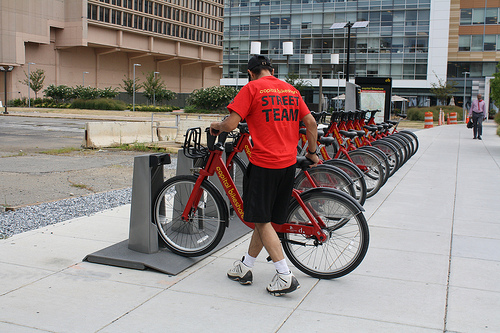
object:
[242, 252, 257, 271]
white sock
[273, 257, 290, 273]
white sock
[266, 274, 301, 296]
foot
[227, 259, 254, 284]
foot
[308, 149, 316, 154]
watch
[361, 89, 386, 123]
large map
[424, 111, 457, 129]
traffic cones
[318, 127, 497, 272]
street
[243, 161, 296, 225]
shorts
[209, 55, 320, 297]
man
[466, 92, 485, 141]
man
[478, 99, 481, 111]
tie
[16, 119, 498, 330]
sidewalk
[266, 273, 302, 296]
shoes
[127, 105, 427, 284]
bikes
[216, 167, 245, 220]
letters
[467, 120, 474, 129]
bag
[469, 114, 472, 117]
hand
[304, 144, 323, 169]
wrist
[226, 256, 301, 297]
feet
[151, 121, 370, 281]
bike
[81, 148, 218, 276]
rack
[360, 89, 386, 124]
display